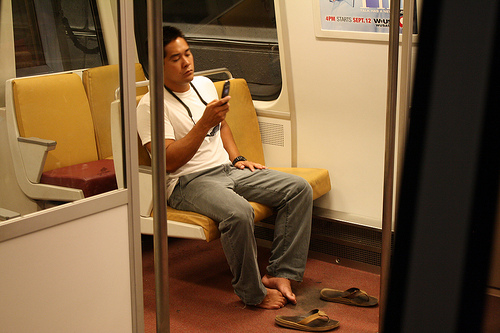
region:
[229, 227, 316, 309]
barefooted man on train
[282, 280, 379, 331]
man's sandals on the floor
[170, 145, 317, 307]
man wearing blue jeans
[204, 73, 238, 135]
man looking at cellphone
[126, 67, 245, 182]
man wearing a white shirt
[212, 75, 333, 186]
yellow backs of train seat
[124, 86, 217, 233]
yellow backs of train seat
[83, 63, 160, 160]
yellow backs of train seat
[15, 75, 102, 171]
yellow backs of train seat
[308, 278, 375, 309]
flip flop on the floor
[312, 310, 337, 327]
thong on the shoe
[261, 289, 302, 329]
toe's by the shoe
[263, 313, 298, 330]
heel of the shoe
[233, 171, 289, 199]
wrinkles in the fabric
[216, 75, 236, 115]
phone in the hand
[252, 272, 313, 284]
hem of the pants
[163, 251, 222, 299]
shadow of the seat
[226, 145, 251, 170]
watch on the wrist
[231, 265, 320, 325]
bare feet on the floor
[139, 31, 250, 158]
the man is texting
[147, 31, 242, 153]
the man is texting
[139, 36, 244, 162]
the man is texting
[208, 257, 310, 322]
the man is barefoot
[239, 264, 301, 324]
the man is barefoot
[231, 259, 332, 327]
the man is barefoot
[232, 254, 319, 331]
the man is barefoot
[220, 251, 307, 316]
the man is barefoot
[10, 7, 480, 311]
This is a subway car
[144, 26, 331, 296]
This is a male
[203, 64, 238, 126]
The man is holding a cell phone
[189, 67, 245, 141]
The cell phone is in his right hand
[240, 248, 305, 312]
The man is barefoot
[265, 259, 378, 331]
His flip flops are on the floor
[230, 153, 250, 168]
A watch on his left wrist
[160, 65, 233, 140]
Sunglasses around his neck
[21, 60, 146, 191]
Yellow and red subway seats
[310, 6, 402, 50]
An advertisement on the wall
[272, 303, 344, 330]
a brown sandal in front of a man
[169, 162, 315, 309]
gray pants in front of a man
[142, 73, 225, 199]
a white shirt on a man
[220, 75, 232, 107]
a phone in a man's hand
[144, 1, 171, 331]
a metal pole across from a man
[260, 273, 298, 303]
a man's bare foot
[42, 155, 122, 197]
a red seat cushion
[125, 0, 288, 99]
a window on a subway car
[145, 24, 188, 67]
black hair on a man's head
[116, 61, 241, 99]
a metal bar on the back of a seat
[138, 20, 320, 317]
man sitting on subway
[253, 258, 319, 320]
bare feet on floor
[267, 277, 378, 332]
empty brown sandals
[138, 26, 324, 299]
man wearing gray jeans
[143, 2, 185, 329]
gray metal subway pole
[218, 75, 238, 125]
black plastic flip phone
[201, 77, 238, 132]
hand holding phone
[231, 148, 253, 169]
black plastic watch on wrist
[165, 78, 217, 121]
black fabric glasses chain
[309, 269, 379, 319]
shoe on the ground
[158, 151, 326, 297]
gray pants on the person